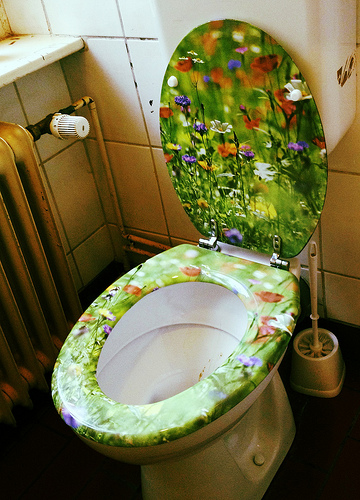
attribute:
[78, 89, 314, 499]
toilet — white, stained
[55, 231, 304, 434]
seat — worn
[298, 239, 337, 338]
brush — white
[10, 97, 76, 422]
radiator — old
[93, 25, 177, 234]
tile — white, old, dirty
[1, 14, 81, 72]
counter — white, rusty, steel, dirty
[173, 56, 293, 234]
flowers — purple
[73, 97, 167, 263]
pipes — metal, rusty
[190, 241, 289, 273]
hinges — silver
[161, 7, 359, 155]
tank — white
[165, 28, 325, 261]
lid — flowery, colored, green, floral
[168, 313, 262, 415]
stain — orange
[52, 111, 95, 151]
vent — white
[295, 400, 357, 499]
floor — brown